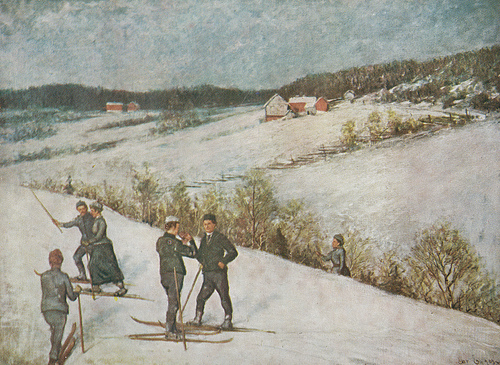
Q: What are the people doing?
A: Skiing.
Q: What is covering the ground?
A: Snow.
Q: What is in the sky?
A: White clouds.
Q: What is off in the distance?
A: A mountain.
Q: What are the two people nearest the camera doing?
A: Talkiing.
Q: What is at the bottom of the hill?
A: Trees.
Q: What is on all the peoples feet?
A: Skis.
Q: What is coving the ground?
A: Snow.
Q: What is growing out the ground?
A: Trees.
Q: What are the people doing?
A: Skiing.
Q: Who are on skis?
A: Five illustrated persons.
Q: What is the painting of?
A: A rural scene with snow and people on skis.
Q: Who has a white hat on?
A: Man on skis.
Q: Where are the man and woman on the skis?
A: In the vintage painting.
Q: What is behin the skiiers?
A: A snow fence across snowy field.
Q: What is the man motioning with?
A: A ski pole.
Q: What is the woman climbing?
A: Snow bank.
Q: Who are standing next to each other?
A: Two men.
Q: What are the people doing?
A: Skiing.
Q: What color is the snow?
A: White.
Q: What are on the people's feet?
A: Skis.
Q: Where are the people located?
A: On the hill.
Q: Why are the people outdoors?
A: To ski.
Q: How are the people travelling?
A: By skis.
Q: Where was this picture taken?
A: Winter.